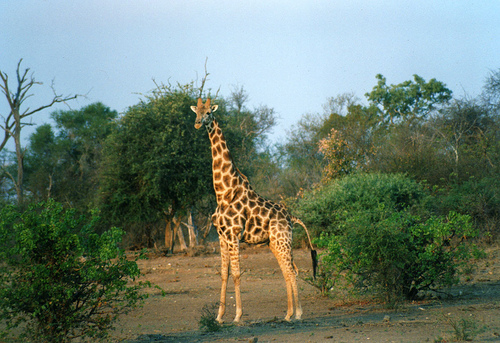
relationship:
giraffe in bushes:
[189, 98, 318, 325] [0, 55, 500, 250]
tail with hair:
[291, 216, 319, 273] [307, 248, 320, 277]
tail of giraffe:
[291, 216, 319, 273] [189, 98, 318, 325]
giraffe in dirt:
[189, 98, 318, 325] [3, 237, 484, 338]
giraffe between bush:
[189, 98, 318, 325] [0, 198, 168, 342]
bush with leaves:
[0, 198, 168, 342] [92, 237, 122, 264]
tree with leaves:
[92, 54, 285, 253] [121, 120, 165, 165]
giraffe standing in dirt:
[169, 106, 338, 316] [266, 320, 303, 338]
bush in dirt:
[282, 169, 494, 307] [361, 308, 401, 340]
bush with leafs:
[282, 169, 494, 307] [389, 205, 417, 234]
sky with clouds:
[311, 20, 377, 54] [249, 10, 319, 30]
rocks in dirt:
[323, 326, 337, 336] [313, 316, 363, 336]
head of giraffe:
[178, 92, 221, 135] [162, 75, 334, 325]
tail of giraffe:
[292, 215, 319, 279] [189, 98, 318, 325]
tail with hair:
[292, 215, 319, 279] [305, 247, 334, 279]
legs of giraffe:
[264, 224, 326, 334] [171, 98, 339, 328]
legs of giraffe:
[217, 224, 246, 321] [176, 100, 322, 319]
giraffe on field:
[189, 98, 318, 325] [2, 235, 498, 341]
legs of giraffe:
[218, 236, 229, 314] [173, 90, 332, 310]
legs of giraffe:
[211, 238, 256, 328] [193, 81, 330, 319]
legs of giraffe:
[253, 220, 317, 322] [191, 98, 339, 318]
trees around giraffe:
[30, 92, 178, 300] [172, 90, 308, 325]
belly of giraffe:
[241, 223, 265, 245] [193, 84, 347, 327]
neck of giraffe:
[187, 123, 241, 193] [195, 75, 336, 326]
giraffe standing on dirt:
[189, 98, 318, 325] [0, 243, 499, 342]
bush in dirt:
[290, 169, 490, 308] [0, 243, 499, 342]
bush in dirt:
[2, 190, 162, 338] [0, 243, 499, 342]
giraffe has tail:
[189, 98, 318, 325] [290, 216, 319, 279]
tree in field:
[90, 56, 278, 251] [2, 241, 499, 341]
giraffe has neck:
[189, 98, 318, 325] [205, 119, 249, 201]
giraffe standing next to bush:
[189, 98, 318, 325] [2, 190, 162, 338]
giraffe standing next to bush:
[189, 98, 318, 325] [292, 164, 481, 304]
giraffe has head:
[189, 98, 318, 325] [185, 96, 219, 126]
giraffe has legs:
[189, 98, 318, 325] [213, 234, 304, 326]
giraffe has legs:
[189, 98, 318, 325] [213, 228, 303, 322]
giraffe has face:
[189, 98, 318, 325] [188, 96, 221, 131]